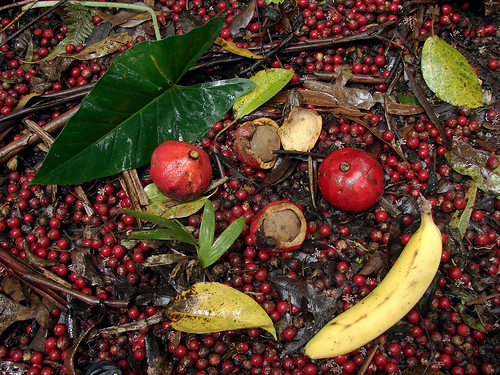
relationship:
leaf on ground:
[47, 19, 252, 162] [3, 7, 488, 354]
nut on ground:
[253, 194, 313, 253] [3, 7, 488, 354]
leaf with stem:
[165, 273, 282, 347] [143, 296, 185, 319]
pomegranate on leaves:
[149, 135, 213, 198] [84, 76, 210, 274]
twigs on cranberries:
[304, 24, 413, 56] [313, 5, 355, 30]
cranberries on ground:
[313, 5, 355, 30] [3, 7, 488, 354]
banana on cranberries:
[305, 205, 452, 357] [313, 5, 355, 30]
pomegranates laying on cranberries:
[147, 137, 384, 231] [313, 5, 355, 30]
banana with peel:
[305, 205, 452, 357] [328, 326, 348, 348]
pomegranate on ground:
[149, 135, 213, 198] [3, 7, 488, 354]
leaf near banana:
[47, 19, 252, 162] [305, 205, 452, 357]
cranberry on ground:
[63, 41, 74, 56] [3, 7, 488, 354]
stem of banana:
[415, 190, 438, 223] [305, 205, 452, 357]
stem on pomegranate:
[188, 147, 201, 160] [149, 135, 213, 198]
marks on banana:
[333, 319, 376, 332] [305, 205, 452, 357]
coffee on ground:
[438, 305, 494, 362] [3, 7, 488, 354]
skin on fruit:
[172, 182, 198, 195] [149, 135, 213, 198]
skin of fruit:
[172, 182, 198, 195] [149, 135, 213, 198]